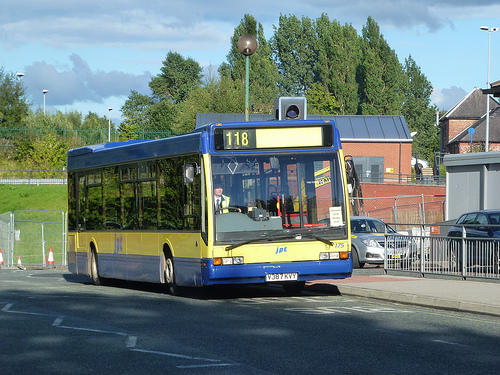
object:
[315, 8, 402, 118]
tree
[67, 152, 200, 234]
windows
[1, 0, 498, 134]
sky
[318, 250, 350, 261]
lights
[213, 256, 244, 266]
lights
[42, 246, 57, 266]
traffic cone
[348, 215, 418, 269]
car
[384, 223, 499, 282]
bicycle rack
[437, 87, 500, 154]
house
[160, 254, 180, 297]
tire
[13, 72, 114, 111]
lights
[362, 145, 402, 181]
ground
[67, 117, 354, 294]
bus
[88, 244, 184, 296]
wheels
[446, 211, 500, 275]
car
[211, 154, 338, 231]
window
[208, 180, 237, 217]
bus driver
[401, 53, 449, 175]
tree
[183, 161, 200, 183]
mirror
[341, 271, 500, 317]
sidewalk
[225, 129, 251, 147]
number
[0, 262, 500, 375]
street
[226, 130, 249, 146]
118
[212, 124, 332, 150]
route number